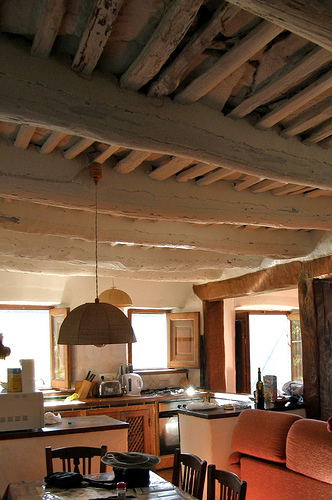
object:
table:
[8, 463, 204, 500]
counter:
[176, 401, 251, 420]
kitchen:
[0, 301, 332, 499]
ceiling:
[0, 0, 332, 281]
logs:
[2, 3, 332, 286]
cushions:
[230, 407, 302, 464]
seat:
[224, 453, 331, 499]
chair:
[205, 463, 247, 498]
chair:
[172, 447, 208, 499]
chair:
[43, 444, 107, 478]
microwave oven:
[0, 385, 44, 438]